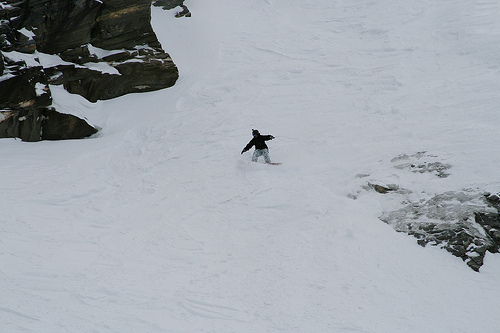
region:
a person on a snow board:
[233, 123, 287, 177]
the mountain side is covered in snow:
[8, 16, 455, 328]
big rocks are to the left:
[6, 3, 189, 141]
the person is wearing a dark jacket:
[243, 118, 270, 148]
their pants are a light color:
[250, 147, 277, 162]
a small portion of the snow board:
[251, 158, 283, 168]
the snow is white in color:
[77, 170, 414, 331]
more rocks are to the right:
[369, 173, 496, 285]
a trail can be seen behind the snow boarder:
[311, 11, 416, 170]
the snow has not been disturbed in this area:
[17, 143, 86, 186]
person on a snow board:
[230, 113, 280, 174]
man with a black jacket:
[238, 138, 277, 150]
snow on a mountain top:
[27, 23, 139, 87]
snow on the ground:
[308, 68, 433, 138]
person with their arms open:
[232, 127, 283, 161]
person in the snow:
[232, 122, 292, 171]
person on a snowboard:
[234, 122, 285, 176]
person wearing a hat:
[244, 123, 266, 140]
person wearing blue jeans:
[244, 145, 283, 162]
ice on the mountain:
[397, 159, 494, 265]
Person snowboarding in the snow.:
[239, 128, 284, 170]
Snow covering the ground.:
[2, 0, 497, 331]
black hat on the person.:
[250, 128, 262, 136]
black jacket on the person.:
[241, 126, 275, 152]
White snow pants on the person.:
[237, 126, 273, 164]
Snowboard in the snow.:
[251, 158, 284, 169]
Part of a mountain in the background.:
[5, 0, 197, 173]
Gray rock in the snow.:
[392, 183, 497, 283]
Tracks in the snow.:
[2, 261, 249, 331]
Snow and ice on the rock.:
[391, 192, 489, 243]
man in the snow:
[233, 120, 288, 170]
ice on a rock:
[396, 166, 499, 264]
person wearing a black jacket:
[241, 137, 281, 152]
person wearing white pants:
[249, 145, 275, 165]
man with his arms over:
[228, 125, 283, 162]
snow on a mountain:
[22, 44, 144, 137]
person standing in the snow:
[228, 114, 290, 179]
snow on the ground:
[310, 41, 480, 178]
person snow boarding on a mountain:
[221, 113, 282, 179]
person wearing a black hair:
[247, 121, 262, 140]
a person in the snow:
[232, 127, 281, 170]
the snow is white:
[67, 190, 323, 318]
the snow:
[110, 210, 341, 323]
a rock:
[437, 221, 482, 264]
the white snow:
[70, 183, 260, 298]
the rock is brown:
[125, 63, 172, 84]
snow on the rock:
[62, 90, 102, 116]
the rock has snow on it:
[10, 45, 71, 75]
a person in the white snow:
[223, 125, 289, 169]